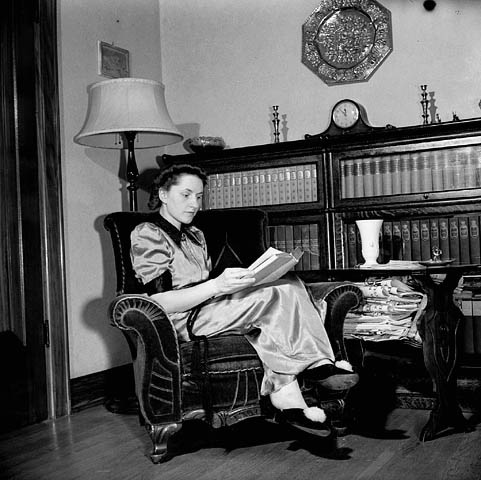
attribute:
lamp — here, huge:
[67, 63, 186, 211]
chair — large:
[97, 209, 344, 450]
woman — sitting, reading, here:
[104, 145, 358, 441]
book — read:
[411, 159, 445, 203]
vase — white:
[352, 207, 382, 270]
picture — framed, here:
[87, 26, 153, 78]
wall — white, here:
[165, 35, 303, 118]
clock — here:
[311, 93, 380, 163]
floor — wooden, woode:
[32, 382, 123, 469]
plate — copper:
[289, 0, 389, 89]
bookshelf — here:
[136, 166, 465, 356]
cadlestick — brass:
[259, 100, 284, 140]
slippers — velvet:
[303, 366, 373, 398]